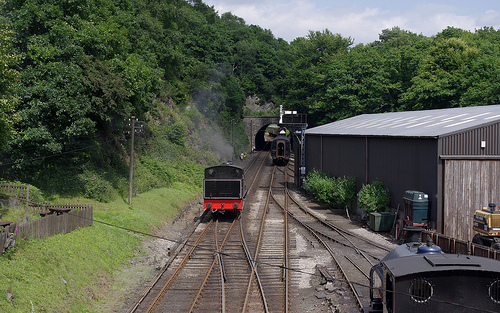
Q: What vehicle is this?
A: Train.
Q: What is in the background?
A: Trees.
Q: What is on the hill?
A: Grass.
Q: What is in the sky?
A: White clouds.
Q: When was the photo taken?
A: In daylight hours.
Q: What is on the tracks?
A: Train cars.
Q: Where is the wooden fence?
A: To the left of the tracks.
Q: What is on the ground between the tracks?
A: Gravel and dirt.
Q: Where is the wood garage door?
A: On the building.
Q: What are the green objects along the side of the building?
A: Bushes.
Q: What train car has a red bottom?
A: The middle one.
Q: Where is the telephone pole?
A: To the left of the tracks.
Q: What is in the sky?
A: Clouds.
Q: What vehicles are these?
A: Trains.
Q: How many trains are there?
A: 2.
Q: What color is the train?
A: Red and black.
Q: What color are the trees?
A: Green.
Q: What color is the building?
A: Gray.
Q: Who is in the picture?
A: No one.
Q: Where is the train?
A: On the track.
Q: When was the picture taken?
A: In the daytime.